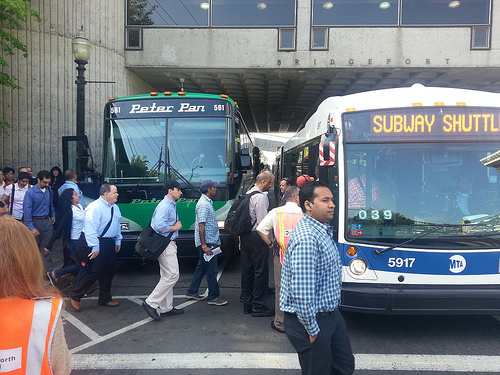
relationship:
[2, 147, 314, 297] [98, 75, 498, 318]
people boarding bus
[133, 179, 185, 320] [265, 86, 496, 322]
man boarding bus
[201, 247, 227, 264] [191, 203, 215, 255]
paper in hand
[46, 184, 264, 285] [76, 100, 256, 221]
people boarding bus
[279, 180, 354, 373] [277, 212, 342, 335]
man in shirt